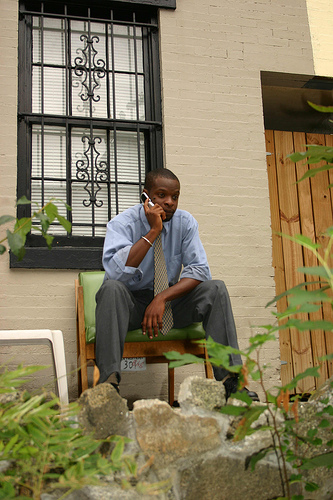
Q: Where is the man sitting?
A: In a chair.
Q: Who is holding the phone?
A: The man.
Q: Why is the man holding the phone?
A: To talk.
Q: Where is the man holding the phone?
A: To his ear.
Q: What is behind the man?
A: Window.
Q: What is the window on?
A: A wall.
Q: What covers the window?
A: Metal.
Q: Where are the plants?
A: In front of the man.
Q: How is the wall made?
A: Bricks.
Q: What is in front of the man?
A: Rocks.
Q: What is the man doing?
A: Speaking on the phone.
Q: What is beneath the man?
A: A chair.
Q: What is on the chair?
A: A green cushion.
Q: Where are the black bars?
A: On the window.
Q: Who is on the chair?
A: The man.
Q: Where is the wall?
A: Behind the man.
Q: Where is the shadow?
A: On the building.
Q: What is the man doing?
A: Talking on the phone.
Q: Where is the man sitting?
A: Outside by a window.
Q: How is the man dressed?
A: Formally.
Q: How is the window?
A: Closed.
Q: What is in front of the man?
A: Rocks and plants.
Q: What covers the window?
A: Black grating.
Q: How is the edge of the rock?
A: Jagged.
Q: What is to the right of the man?
A: A wooden fence.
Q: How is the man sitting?
A: With his legs open.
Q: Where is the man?
A: On the porch.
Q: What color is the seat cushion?
A: Green.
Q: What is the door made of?
A: Wood.